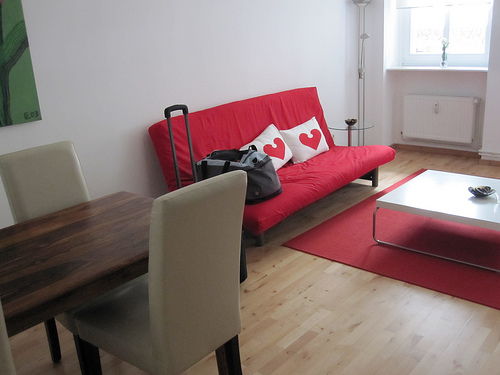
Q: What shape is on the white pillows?
A: Heart.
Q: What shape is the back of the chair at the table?
A: Rectangle.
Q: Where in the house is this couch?
A: Living room.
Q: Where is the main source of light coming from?
A: Window.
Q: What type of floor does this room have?
A: Wooden.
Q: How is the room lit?
A: Sunlight.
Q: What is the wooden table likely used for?
A: Eating.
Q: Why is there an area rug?
A: Decoration.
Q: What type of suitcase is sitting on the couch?
A: Duffle bag.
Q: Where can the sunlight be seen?
A: Window.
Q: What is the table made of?
A: Wood.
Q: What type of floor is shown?
A: Hardwood.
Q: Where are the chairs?
A: Each side of the table.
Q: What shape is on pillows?
A: Hearts.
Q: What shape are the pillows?
A: Square.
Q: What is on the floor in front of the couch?
A: Rug.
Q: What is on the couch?
A: Duffle bag.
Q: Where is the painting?
A: Behind the table.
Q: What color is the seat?
A: Red.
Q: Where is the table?
A: Next the chairs.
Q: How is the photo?
A: Clear.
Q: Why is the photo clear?
A: It's during the day.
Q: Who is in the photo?
A: Nobody.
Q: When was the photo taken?
A: Daytime.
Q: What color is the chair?
A: Grey.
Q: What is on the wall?
A: A picture.